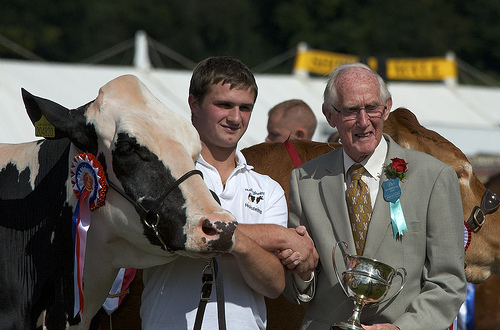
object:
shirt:
[140, 150, 290, 330]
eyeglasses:
[337, 103, 387, 123]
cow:
[0, 74, 243, 330]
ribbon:
[65, 152, 109, 323]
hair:
[188, 55, 262, 110]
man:
[274, 55, 468, 329]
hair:
[316, 60, 393, 105]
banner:
[296, 47, 456, 84]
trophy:
[329, 240, 409, 330]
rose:
[386, 153, 408, 181]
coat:
[284, 134, 469, 329]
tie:
[344, 161, 372, 256]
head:
[22, 72, 240, 271]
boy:
[140, 57, 319, 330]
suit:
[288, 130, 468, 330]